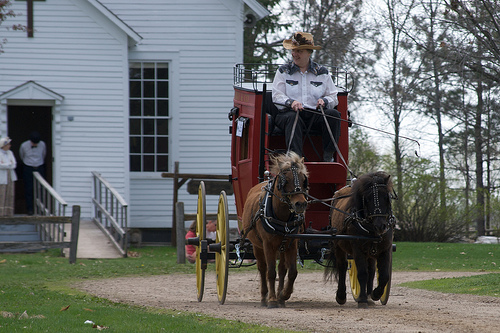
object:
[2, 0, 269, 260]
church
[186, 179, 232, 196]
sign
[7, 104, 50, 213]
doorway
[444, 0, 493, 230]
tree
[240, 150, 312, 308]
horse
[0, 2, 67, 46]
cross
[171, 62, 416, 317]
couch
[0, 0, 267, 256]
building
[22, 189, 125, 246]
ramp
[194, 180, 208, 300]
wheel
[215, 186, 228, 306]
wheel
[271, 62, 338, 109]
shirt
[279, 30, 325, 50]
cowboy hat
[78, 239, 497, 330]
path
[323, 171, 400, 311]
horse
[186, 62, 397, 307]
cart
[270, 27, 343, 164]
man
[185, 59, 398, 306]
carriage